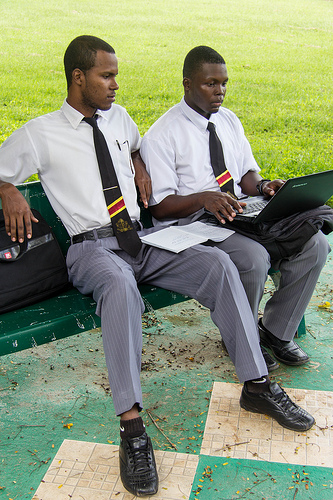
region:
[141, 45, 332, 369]
a man using a laptop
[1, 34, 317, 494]
a man sitting on a bench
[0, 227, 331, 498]
green concrete around a bench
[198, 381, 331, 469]
a white tiled square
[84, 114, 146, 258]
a black tie with yellow and red stripes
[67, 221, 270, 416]
gray pants on a man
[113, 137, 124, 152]
a pen in a man's pocket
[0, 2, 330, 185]
a grassy field behind two men on a bench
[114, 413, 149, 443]
a black sock with a white Nike emblem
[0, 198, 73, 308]
a black bag on a bench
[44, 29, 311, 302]
two man sitting on bench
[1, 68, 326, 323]
two men on a green bench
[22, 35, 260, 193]
two men with short hair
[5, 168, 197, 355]
a bag next to a man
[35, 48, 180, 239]
a man wearing a tie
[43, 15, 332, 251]
two men wearing a tie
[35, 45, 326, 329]
two men wearing pants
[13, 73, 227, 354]
a man wearing a belt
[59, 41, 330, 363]
two men wearing shoes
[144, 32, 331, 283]
a man on a laptop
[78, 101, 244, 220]
men wearing black ties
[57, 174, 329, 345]
men's pants are gray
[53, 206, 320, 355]
men's pants are striped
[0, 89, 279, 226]
men wearing white shirts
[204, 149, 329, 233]
man holding a laptop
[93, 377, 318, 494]
man's shoes are black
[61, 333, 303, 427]
man's socks are black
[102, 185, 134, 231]
red and yellow stripes on tie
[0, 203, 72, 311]
black bag next to man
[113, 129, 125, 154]
pen in man's shirt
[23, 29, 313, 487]
two boys sitting on bench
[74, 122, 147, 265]
black tie with stripes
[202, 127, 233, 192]
black tie with stripes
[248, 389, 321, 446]
black shoe on boy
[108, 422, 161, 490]
black shoe on boy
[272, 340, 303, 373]
black shoe on boy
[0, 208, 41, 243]
right hand of boy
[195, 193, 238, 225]
right hand of boy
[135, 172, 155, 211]
left hand of boy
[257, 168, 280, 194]
left hand of boy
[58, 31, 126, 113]
the head of a man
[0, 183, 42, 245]
the hand of a man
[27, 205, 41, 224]
the thumb of a man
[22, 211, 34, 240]
the finger of a man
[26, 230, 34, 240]
the finger nail of a man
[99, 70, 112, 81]
the eye of a man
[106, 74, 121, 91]
the nose of a man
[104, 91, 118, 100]
the mouth of a man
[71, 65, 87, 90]
the ear of a man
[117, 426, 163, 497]
a black shoe on the man